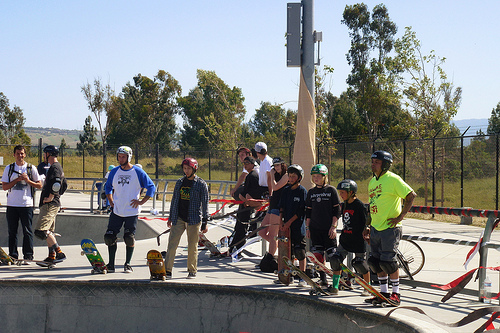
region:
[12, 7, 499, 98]
bright sunny day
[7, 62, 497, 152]
trees behind the skate park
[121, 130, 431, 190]
skaters wearing safety helmets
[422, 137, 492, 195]
fence around skate park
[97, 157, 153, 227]
skater with his hands on hips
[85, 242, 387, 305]
skateboard wheels in the air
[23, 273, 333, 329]
gray skateboard ramp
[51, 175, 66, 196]
skater wearing elbow pads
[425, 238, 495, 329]
streamer waving in the air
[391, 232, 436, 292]
bicycle behind the skaters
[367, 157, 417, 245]
the shirt is green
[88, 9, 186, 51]
the sky is clear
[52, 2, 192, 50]
the sky is blue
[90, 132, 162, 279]
the shirt is blue and white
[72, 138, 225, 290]
the people will skate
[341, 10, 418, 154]
the trees are green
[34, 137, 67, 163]
the helmet is black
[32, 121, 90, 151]
the hill is far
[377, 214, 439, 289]
the bike is parked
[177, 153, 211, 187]
the helmet is red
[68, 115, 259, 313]
Skaters at a skate park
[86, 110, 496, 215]
Skater wearing helmets.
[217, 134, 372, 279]
People watching other skaters.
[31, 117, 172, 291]
Skater ready to go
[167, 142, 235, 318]
Skater with a red helmet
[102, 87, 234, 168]
Trees behind the skate park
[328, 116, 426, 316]
Skater wearing a yellow shirt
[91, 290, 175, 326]
Skater going on the half pipe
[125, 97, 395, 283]
Group of people at the skate park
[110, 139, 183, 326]
Skateboard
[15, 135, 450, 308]
people on ground level of skate park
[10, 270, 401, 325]
rim on top of wall to lower elevation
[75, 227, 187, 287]
tips of skateboards pointing up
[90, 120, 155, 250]
man wearing helmet with hands on hips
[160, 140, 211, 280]
person with red helmet with arms at side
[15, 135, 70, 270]
person turned toward another person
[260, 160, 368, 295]
three children in dark clothes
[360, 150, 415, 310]
man in bright shirt with hand on waist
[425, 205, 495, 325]
black and red streamers flying in breeze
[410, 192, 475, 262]
railing wrapped in red or white ribbons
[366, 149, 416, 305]
a man wearing a yellow shirt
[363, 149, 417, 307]
a man wearing a black helmet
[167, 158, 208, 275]
a man wearing a red helmet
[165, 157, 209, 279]
a man wearing tan pants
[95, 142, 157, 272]
a man wearing a white and blue shirt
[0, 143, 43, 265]
a man wearing a white shirt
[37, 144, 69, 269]
a man wearing a black shirt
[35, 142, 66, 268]
a man wearing tan shorts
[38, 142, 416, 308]
a group of skateboarders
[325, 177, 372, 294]
a person wearing green socks